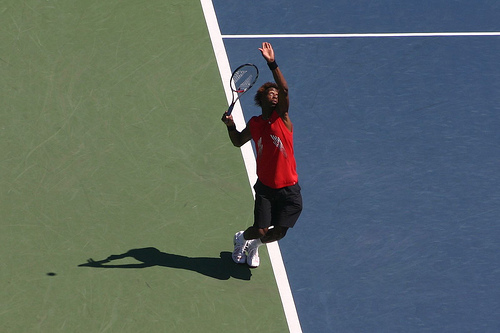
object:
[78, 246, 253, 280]
shadow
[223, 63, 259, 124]
racket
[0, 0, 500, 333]
court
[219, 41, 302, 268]
man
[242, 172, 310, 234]
shorts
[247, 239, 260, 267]
tennis shoes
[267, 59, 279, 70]
wristband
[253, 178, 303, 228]
shorts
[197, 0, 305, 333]
line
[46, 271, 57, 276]
shadow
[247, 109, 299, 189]
tank top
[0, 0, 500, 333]
game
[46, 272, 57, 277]
ball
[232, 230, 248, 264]
shoes